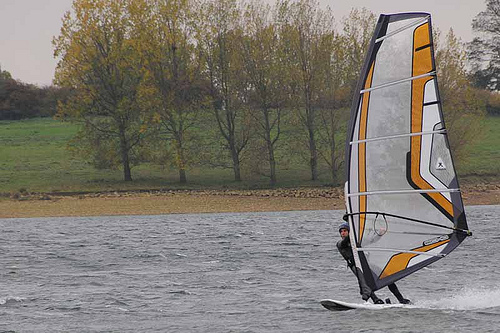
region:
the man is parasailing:
[315, 1, 469, 331]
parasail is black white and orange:
[322, 10, 479, 297]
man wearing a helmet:
[331, 219, 353, 246]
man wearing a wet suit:
[337, 238, 423, 314]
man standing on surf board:
[305, 220, 420, 323]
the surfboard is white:
[320, 293, 443, 325]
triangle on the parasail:
[429, 152, 448, 180]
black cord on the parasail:
[340, 196, 471, 239]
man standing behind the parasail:
[332, 221, 413, 312]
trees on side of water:
[50, 1, 487, 183]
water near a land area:
[8, 213, 487, 323]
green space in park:
[6, 120, 488, 183]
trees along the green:
[48, 2, 477, 170]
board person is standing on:
[299, 293, 437, 320]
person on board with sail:
[319, 8, 481, 321]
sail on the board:
[340, 7, 472, 284]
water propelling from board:
[421, 285, 499, 311]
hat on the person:
[333, 218, 351, 228]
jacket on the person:
[338, 237, 356, 260]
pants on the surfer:
[356, 278, 406, 308]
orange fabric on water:
[359, 217, 366, 235]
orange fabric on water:
[360, 171, 364, 184]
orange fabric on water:
[420, 244, 432, 249]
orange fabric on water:
[412, 148, 419, 173]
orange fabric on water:
[415, 85, 420, 117]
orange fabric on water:
[356, 78, 376, 80]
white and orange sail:
[342, 9, 472, 284]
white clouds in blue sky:
[15, 25, 73, 95]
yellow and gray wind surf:
[343, 12, 466, 290]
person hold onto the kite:
[325, 210, 377, 310]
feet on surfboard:
[317, 299, 433, 324]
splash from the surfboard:
[422, 287, 494, 317]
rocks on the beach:
[68, 192, 330, 199]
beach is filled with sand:
[31, 197, 307, 208]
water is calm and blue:
[0, 219, 329, 309]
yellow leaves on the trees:
[60, 4, 357, 99]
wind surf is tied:
[350, 58, 452, 215]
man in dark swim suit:
[334, 222, 364, 283]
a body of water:
[70, 225, 245, 330]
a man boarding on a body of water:
[320, 209, 402, 307]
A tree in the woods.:
[60, 10, 162, 188]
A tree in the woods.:
[121, 4, 219, 194]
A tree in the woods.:
[171, 2, 266, 187]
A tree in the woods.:
[216, 0, 305, 191]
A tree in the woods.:
[252, 0, 348, 190]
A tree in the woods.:
[308, 0, 368, 190]